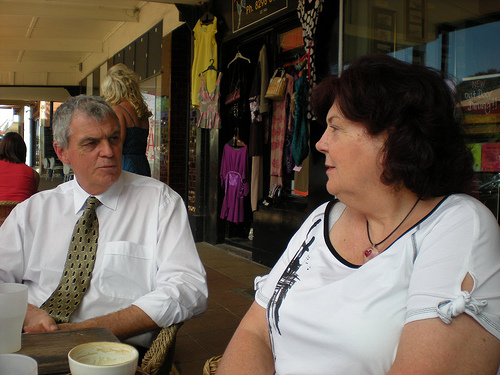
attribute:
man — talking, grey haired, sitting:
[1, 97, 209, 358]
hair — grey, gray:
[50, 99, 119, 148]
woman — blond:
[103, 65, 151, 176]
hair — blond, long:
[102, 64, 147, 119]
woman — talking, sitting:
[211, 55, 499, 372]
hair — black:
[310, 54, 474, 198]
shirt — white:
[253, 199, 498, 373]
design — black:
[264, 212, 322, 367]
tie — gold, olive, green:
[42, 197, 101, 326]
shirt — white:
[0, 174, 208, 362]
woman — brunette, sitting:
[0, 131, 40, 201]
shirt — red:
[0, 164, 33, 202]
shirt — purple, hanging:
[218, 144, 248, 224]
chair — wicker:
[139, 327, 182, 373]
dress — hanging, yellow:
[189, 16, 218, 100]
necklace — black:
[364, 190, 426, 242]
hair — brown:
[0, 133, 28, 165]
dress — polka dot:
[297, 0, 320, 116]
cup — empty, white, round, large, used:
[68, 340, 136, 374]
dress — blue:
[121, 101, 150, 174]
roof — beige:
[0, 0, 163, 87]